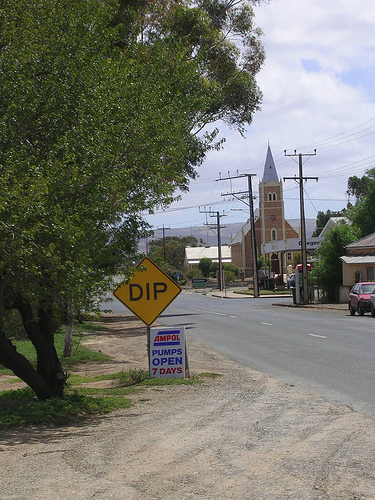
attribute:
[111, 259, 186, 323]
sign — yellow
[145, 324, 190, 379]
sign — white, red, small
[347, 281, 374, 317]
car — parked, read, red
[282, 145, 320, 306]
pole — wooden, tall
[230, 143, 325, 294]
church — tall, brick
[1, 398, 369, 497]
road — dirt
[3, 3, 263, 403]
tree — green, large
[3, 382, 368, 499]
driveway — gravel, dirt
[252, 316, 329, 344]
lines — white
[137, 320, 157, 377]
pole — metal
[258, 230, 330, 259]
covering — white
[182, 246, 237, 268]
roof — gray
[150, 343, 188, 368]
words — blue